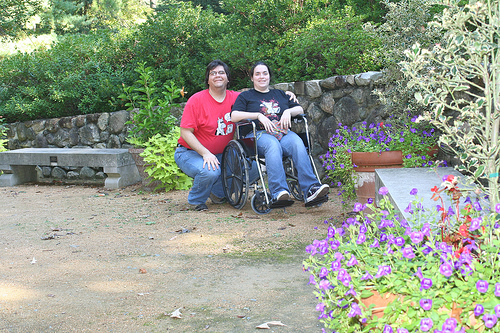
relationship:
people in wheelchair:
[231, 60, 333, 204] [213, 111, 321, 194]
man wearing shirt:
[174, 58, 263, 211] [172, 81, 229, 151]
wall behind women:
[4, 101, 125, 164] [167, 70, 337, 185]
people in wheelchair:
[231, 60, 333, 204] [217, 123, 358, 247]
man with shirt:
[174, 58, 263, 211] [179, 101, 249, 169]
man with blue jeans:
[174, 58, 263, 211] [172, 142, 245, 204]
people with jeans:
[231, 60, 333, 204] [245, 120, 339, 202]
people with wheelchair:
[231, 60, 333, 204] [225, 118, 356, 242]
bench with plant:
[2, 130, 154, 190] [127, 81, 200, 180]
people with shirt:
[231, 60, 333, 204] [225, 87, 315, 126]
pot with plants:
[116, 148, 186, 204] [109, 73, 199, 157]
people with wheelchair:
[231, 60, 333, 204] [223, 123, 344, 213]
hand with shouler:
[252, 120, 284, 143] [263, 74, 315, 112]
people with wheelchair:
[231, 60, 333, 204] [217, 117, 353, 190]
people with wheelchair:
[231, 60, 333, 204] [216, 130, 360, 220]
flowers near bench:
[301, 172, 499, 326] [368, 161, 488, 235]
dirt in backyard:
[64, 250, 214, 310] [0, 0, 500, 332]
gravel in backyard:
[32, 219, 82, 248] [0, 0, 500, 332]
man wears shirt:
[168, 55, 240, 211] [176, 89, 243, 154]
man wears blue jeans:
[168, 55, 240, 211] [168, 146, 246, 204]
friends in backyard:
[168, 56, 335, 214] [0, 0, 500, 332]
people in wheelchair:
[231, 60, 333, 204] [224, 109, 329, 216]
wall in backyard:
[269, 68, 426, 185] [0, 0, 500, 332]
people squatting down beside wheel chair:
[231, 60, 333, 204] [219, 113, 329, 212]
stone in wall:
[308, 103, 329, 126] [3, 69, 431, 183]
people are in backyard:
[166, 53, 334, 222] [0, 0, 500, 332]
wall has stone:
[269, 68, 426, 185] [304, 75, 325, 100]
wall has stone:
[306, 65, 378, 130] [351, 84, 368, 107]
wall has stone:
[269, 68, 426, 185] [319, 94, 335, 112]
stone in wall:
[304, 80, 325, 98] [294, 70, 377, 120]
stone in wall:
[304, 80, 325, 98] [304, 68, 385, 139]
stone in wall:
[107, 110, 130, 133] [52, 107, 124, 140]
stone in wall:
[107, 110, 129, 137] [31, 110, 121, 145]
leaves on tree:
[194, 30, 230, 56] [120, 10, 243, 69]